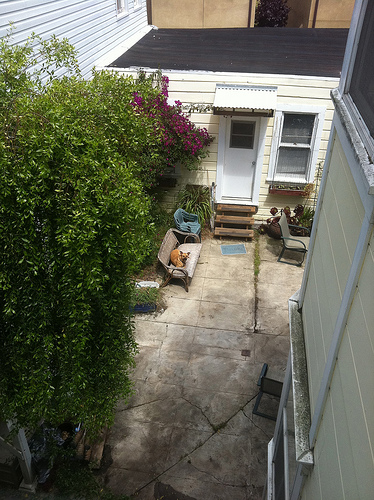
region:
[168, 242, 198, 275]
a dog on a couch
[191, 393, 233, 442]
a crack in the walkway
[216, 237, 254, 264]
a rug on the ground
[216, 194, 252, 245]
steps going into the house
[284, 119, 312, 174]
a window on a house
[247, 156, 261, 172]
a doorknob on a door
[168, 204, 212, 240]
a cahir on the ground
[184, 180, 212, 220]
a plant growing beside the house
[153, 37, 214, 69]
a black roof on the house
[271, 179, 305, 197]
a flower box on the window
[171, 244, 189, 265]
dog on a bench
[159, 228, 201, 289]
a gray bench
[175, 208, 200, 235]
stack of blue plastic chairs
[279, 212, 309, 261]
a brown chair on the right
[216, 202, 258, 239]
wooden steps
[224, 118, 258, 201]
a white door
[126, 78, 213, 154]
purple flowers by the door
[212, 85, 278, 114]
white awning over door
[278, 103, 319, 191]
window next to door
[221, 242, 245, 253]
blue door mat on the ground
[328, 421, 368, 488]
White colored wooden wall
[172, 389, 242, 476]
Cracked grey yard floor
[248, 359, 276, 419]
Carelessly lying wooden chair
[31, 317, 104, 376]
Thick green growing tree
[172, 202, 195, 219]
Sky blue arm chair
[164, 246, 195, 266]
Dog lying on seat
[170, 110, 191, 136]
Beautiful pink bouganvillea flowers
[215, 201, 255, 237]
Three wooden house stairs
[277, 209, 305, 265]
An empty arm chair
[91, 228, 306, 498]
a concrete ground surface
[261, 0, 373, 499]
the exterior of a house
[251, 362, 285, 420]
an outdoor patio chair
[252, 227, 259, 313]
a row of weeds on the ground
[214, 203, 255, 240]
a small wooden stairway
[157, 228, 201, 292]
an outdoor wicker bench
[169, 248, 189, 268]
a dog on the bench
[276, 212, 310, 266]
a patio chair on the concrete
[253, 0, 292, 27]
a tree in the background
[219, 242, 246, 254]
a small blue doormat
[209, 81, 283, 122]
a small awning over the door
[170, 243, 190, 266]
a dog laying on the patio furniture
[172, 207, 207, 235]
a blue patio chair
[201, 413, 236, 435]
a large crack in the patio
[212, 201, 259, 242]
set of steps below the door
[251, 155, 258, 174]
the handle on the door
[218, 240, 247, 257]
a small blue mat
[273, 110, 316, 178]
a window on the house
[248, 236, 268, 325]
grass growing on the patio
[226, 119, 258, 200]
a white door on the house